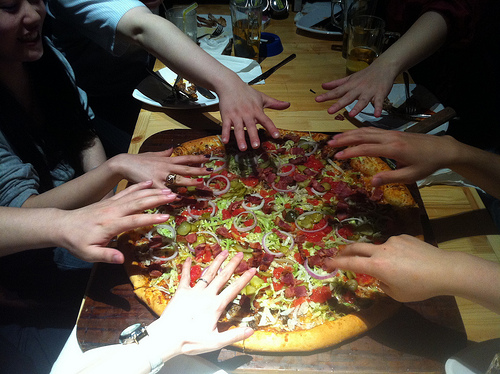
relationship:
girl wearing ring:
[2, 1, 221, 264] [163, 172, 177, 186]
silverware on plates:
[143, 65, 206, 108] [131, 62, 243, 104]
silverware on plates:
[192, 24, 225, 43] [176, 11, 245, 48]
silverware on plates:
[397, 70, 416, 116] [339, 78, 451, 140]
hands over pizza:
[162, 247, 260, 354] [123, 123, 425, 354]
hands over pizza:
[68, 177, 180, 270] [123, 123, 425, 354]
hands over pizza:
[117, 145, 216, 204] [123, 123, 425, 354]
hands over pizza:
[213, 83, 293, 152] [123, 123, 425, 354]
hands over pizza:
[313, 63, 397, 124] [123, 123, 425, 354]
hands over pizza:
[327, 127, 454, 189] [123, 123, 425, 354]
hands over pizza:
[322, 231, 452, 310] [123, 123, 425, 354]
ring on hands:
[163, 172, 177, 186] [117, 145, 216, 204]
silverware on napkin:
[192, 24, 225, 43] [197, 34, 227, 55]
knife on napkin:
[249, 50, 298, 84] [207, 51, 265, 87]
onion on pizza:
[232, 210, 256, 232] [123, 123, 425, 354]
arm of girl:
[1, 134, 213, 212] [2, 1, 221, 264]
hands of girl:
[117, 145, 216, 204] [2, 1, 221, 264]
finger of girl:
[171, 151, 212, 164] [2, 1, 221, 264]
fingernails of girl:
[202, 152, 212, 161] [2, 1, 221, 264]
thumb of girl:
[146, 144, 177, 159] [2, 1, 221, 264]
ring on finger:
[163, 172, 177, 186] [161, 172, 204, 190]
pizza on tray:
[123, 123, 425, 354] [76, 123, 474, 373]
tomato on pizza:
[222, 204, 231, 219] [123, 123, 425, 354]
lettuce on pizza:
[221, 237, 233, 250] [123, 123, 425, 354]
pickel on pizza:
[175, 218, 192, 236] [123, 123, 425, 354]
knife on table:
[249, 50, 298, 84] [47, 2, 500, 373]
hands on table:
[117, 145, 216, 204] [47, 2, 500, 373]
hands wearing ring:
[117, 145, 216, 204] [163, 172, 177, 186]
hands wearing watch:
[162, 247, 260, 354] [116, 321, 166, 373]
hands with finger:
[117, 145, 216, 204] [171, 151, 212, 164]